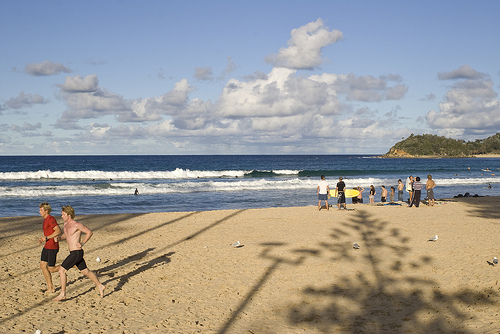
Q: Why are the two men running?
A: Exercise.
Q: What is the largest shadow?
A: Tree.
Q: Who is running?
A: Two guys.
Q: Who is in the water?
A: Some people.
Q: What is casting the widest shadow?
A: A tree.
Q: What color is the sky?
A: Blue.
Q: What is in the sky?
A: Clouds.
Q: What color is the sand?
A: Tan.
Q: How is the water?
A: Wavy.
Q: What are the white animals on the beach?
A: Birds.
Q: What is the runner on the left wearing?
A: A red shirt and black shorts.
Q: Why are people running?
A: Exercise.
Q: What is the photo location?
A: Beach.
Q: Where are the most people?
A: Shoreline.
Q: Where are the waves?
A: Ocean.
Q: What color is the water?
A: Blue.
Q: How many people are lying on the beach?
A: Zero.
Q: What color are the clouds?
A: Grey.